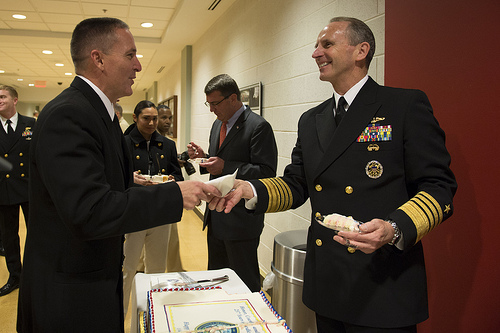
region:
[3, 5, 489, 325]
people in business suits and military uniforms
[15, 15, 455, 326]
men speaking to each other over a cake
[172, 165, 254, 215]
two hands touching white napkin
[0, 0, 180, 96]
tiled ceiling with white lights on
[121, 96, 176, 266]
officer holding plate of food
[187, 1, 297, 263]
man standing near painted block wall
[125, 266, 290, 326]
decorated white cake on white table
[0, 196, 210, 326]
people standing on tan floor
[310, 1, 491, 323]
red wall in back of officer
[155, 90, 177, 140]
man in front of framed glass panels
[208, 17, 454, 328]
A man in a uniform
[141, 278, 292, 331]
A big cake for a celebration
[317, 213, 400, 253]
Cake is on a plate in a man's hand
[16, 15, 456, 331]
A man is handing a slice of cake to another man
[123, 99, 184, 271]
A women has on a black jacket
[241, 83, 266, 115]
A frame is on the wall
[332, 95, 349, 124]
A black tie on the man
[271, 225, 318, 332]
A silver trash can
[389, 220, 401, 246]
A watch on the man's wrist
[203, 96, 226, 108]
Glasses being worn by the man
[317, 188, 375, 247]
The man has a piece of cake in hand.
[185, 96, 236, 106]
The man is wearing glasses.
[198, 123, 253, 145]
The man is wearing a red tie.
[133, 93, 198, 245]
The lady is watchng the man.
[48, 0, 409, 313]
People standing around each other.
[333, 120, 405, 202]
The jacket has military badges and pins on it.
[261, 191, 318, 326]
A silver garbarge can next to the man.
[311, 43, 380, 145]
The man is smiling.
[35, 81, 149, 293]
The man is wearing a black suit.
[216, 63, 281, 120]
A picture on the wall.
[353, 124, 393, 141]
multicolored military award ribbons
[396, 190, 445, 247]
gold colored rank stripes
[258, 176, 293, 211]
gold colored rank stripes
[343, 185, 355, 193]
small gold jacket button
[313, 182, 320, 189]
small gold jacket button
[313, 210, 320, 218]
small gold jacket button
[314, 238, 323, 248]
small gold jacket button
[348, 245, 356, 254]
small gold jacket button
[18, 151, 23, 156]
small gold jacket button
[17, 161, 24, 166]
small gold jacket button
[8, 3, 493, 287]
men wearing uniforms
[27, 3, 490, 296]
men wearing suits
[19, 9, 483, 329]
men smiling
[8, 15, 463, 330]
two men that are smiling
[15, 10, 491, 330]
men that are holding plates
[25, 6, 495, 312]
men holding plates of food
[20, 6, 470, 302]
men with short hair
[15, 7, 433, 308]
men in suits and uniform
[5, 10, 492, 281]
men talking to each other